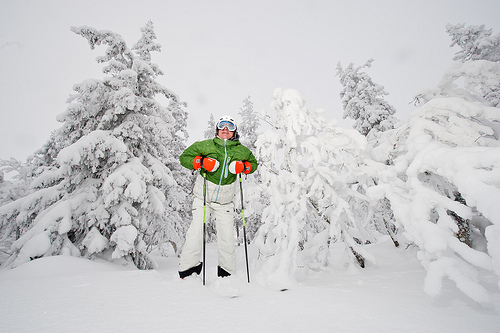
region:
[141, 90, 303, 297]
a man standing in the snow.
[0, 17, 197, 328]
a snow covered tree.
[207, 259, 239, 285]
a man wearing a black shoe.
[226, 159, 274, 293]
a person holding a ski pole.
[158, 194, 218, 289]
a right leg of a person.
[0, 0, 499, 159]
a white sky filled with snow.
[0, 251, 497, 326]
snow covered ground under trees.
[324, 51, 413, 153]
a tall snow covered tree.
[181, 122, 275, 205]
a green and white jacket.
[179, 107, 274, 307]
a skier standing in the snow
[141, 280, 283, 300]
skis covered in snow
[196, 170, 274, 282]
a pair of ski poles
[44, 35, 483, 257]
trees covered in snow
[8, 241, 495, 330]
Snow covering the ground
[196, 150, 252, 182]
orange and white gloves on the skier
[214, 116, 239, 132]
goggles on the skier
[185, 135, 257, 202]
green and white jacket on the skier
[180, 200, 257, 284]
white pants on the skier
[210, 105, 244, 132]
a white helmet on the skier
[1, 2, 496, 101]
The sky is very overcast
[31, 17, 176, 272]
trees covered with snow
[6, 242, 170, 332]
deep snow on the ground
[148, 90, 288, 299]
A person holding poles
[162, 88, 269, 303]
The person is wearing goggles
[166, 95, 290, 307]
The person is wearing a white and green coat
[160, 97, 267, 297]
The person is wearing orange and white gloves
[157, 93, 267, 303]
The person is wearing white pants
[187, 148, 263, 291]
The poles are black and green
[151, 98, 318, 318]
The person is skiing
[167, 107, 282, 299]
The person is holding ski poles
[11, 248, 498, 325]
The ground is covered in snow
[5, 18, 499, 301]
The trees are covered in snow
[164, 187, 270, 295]
The person is wearing white pants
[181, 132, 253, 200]
The person is wearing a green and white jacket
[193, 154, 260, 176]
The person is wearing white and red gloves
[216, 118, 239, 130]
The person is wearing goggles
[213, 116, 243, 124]
The person is wearing a helmet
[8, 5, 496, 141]
The sky is gray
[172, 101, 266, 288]
man standing on a snowy hill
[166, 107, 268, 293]
man wears a green and white jacket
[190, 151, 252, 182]
two gloves color orange and white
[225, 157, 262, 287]
snow pole on left hand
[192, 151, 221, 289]
snow pole on right hand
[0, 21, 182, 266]
tree is covered with snow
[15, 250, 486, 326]
hill is covered with snow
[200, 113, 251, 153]
woman wears a white helmet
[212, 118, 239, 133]
goggles on face of woman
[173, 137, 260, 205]
the lower part of jacket is white